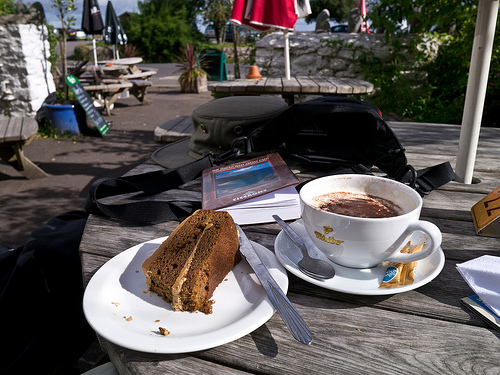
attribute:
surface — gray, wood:
[351, 304, 478, 374]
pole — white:
[439, 49, 499, 161]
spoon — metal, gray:
[267, 207, 339, 293]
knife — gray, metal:
[230, 221, 316, 348]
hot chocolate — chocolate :
[326, 189, 398, 220]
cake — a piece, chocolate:
[139, 207, 242, 318]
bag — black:
[158, 40, 453, 188]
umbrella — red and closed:
[227, 0, 317, 34]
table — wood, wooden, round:
[75, 112, 497, 373]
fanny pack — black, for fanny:
[188, 89, 459, 199]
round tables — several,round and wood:
[78, 118, 499, 373]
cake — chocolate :
[149, 202, 251, 311]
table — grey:
[315, 311, 454, 363]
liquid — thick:
[304, 173, 410, 224]